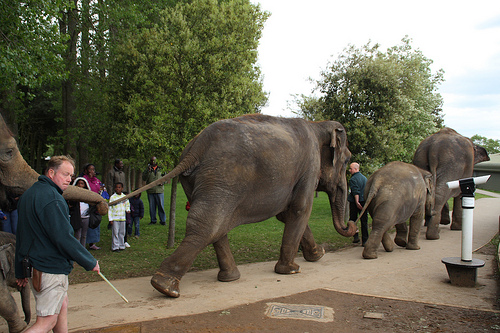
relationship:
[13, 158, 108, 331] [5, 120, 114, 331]
man walking beside elephant